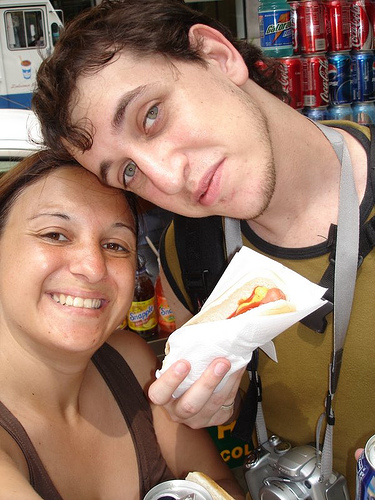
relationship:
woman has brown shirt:
[4, 145, 237, 499] [0, 346, 170, 497]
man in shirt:
[38, 4, 375, 489] [167, 119, 374, 488]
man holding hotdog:
[38, 4, 375, 489] [160, 289, 299, 382]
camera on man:
[241, 434, 350, 498] [38, 4, 375, 489]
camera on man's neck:
[241, 434, 350, 498] [270, 96, 353, 250]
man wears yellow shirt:
[38, 4, 375, 489] [167, 119, 374, 488]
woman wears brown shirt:
[4, 145, 237, 499] [0, 346, 170, 497]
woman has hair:
[4, 145, 237, 499] [0, 141, 81, 209]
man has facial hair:
[38, 4, 375, 489] [252, 87, 274, 227]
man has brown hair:
[38, 4, 375, 489] [42, 0, 310, 148]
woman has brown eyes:
[4, 145, 237, 499] [34, 226, 135, 254]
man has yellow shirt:
[38, 4, 375, 489] [167, 119, 374, 488]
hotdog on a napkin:
[160, 289, 299, 382] [149, 248, 326, 420]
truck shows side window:
[3, 7, 75, 168] [0, 9, 51, 53]